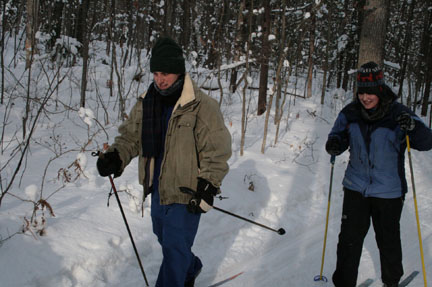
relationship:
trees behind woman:
[0, 1, 430, 141] [313, 56, 432, 286]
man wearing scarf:
[95, 34, 234, 286] [137, 70, 190, 161]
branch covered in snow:
[48, 94, 111, 142] [78, 105, 97, 127]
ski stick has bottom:
[312, 153, 338, 287] [313, 273, 328, 285]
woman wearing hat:
[313, 56, 432, 286] [354, 60, 399, 106]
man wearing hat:
[95, 34, 234, 286] [146, 36, 187, 77]